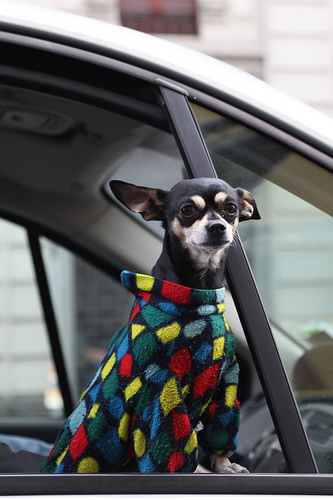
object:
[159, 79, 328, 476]
trim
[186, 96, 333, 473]
window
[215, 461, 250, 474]
paw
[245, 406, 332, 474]
panel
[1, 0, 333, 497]
car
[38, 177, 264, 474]
dog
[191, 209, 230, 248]
snout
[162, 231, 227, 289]
neck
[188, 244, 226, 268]
patch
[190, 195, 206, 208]
eye brow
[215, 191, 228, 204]
eye brow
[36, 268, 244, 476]
jacket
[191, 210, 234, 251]
muzzle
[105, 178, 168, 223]
ear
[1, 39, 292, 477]
window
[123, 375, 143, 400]
square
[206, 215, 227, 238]
nose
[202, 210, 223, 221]
center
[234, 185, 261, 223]
ear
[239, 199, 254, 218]
inside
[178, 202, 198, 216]
eye